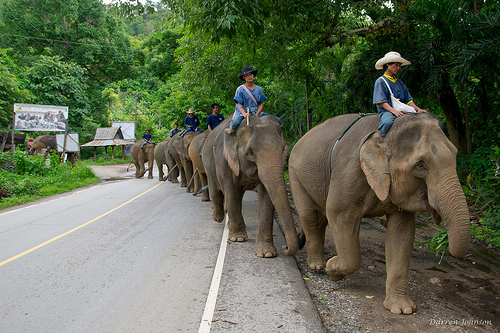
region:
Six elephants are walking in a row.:
[129, 113, 476, 312]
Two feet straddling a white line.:
[211, 190, 250, 242]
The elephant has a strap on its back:
[319, 110, 404, 227]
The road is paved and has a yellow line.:
[0, 160, 327, 327]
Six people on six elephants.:
[130, 47, 474, 314]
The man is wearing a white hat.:
[371, 49, 416, 120]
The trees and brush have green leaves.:
[3, 1, 498, 248]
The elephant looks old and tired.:
[356, 112, 473, 287]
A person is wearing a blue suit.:
[226, 83, 268, 136]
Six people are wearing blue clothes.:
[136, 67, 421, 145]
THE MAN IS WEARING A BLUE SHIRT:
[367, 75, 414, 118]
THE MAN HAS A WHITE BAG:
[373, 75, 414, 115]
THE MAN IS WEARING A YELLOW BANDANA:
[380, 72, 395, 82]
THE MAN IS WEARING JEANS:
[372, 110, 403, 146]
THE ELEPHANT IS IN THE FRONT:
[280, 103, 476, 313]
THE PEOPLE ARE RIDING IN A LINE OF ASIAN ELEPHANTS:
[125, 45, 475, 318]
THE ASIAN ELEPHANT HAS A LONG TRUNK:
[256, 152, 296, 253]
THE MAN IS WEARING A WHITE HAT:
[370, 45, 410, 71]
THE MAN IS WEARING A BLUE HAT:
[236, 61, 256, 76]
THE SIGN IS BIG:
[6, 98, 91, 145]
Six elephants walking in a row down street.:
[126, 106, 496, 315]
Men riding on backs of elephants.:
[175, 64, 285, 142]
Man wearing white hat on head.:
[371, 48, 412, 71]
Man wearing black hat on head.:
[236, 62, 260, 81]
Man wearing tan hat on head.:
[183, 102, 200, 116]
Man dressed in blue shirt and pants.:
[225, 84, 273, 133]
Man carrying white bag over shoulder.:
[379, 75, 419, 117]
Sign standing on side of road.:
[6, 98, 72, 175]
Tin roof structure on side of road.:
[81, 116, 133, 161]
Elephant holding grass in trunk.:
[416, 218, 474, 266]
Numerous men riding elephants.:
[135, 99, 487, 299]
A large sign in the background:
[14, 99, 74, 136]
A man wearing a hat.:
[378, 45, 413, 81]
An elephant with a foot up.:
[323, 243, 355, 280]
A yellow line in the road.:
[29, 183, 176, 290]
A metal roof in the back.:
[82, 118, 128, 150]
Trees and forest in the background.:
[21, 22, 222, 87]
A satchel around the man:
[377, 77, 413, 112]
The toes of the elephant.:
[393, 305, 419, 318]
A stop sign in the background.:
[26, 136, 36, 144]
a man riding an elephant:
[316, 39, 433, 259]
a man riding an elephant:
[211, 54, 301, 194]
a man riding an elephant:
[191, 85, 223, 210]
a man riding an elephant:
[178, 99, 196, 156]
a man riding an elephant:
[115, 115, 172, 187]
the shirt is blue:
[352, 74, 412, 123]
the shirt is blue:
[232, 86, 279, 121]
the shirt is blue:
[208, 108, 229, 123]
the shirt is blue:
[179, 108, 203, 135]